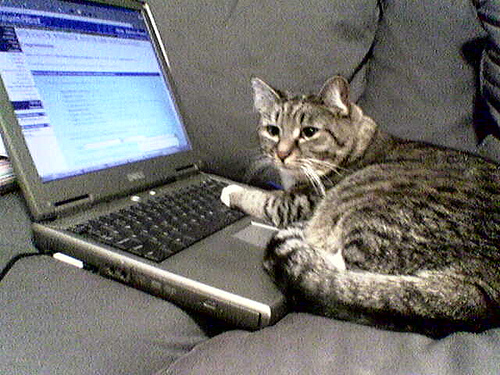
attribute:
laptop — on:
[3, 1, 215, 205]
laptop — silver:
[0, 1, 317, 332]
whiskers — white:
[240, 157, 343, 206]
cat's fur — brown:
[201, 67, 498, 332]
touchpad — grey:
[234, 221, 287, 249]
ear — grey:
[315, 72, 353, 115]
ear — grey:
[247, 70, 288, 113]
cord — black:
[4, 247, 54, 282]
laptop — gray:
[7, 0, 307, 307]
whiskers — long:
[229, 146, 341, 191]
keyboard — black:
[118, 152, 268, 274]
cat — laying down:
[231, 72, 480, 291]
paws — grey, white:
[215, 180, 275, 222]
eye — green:
[258, 122, 281, 139]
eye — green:
[296, 125, 318, 141]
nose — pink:
[275, 140, 294, 160]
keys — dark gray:
[59, 177, 249, 265]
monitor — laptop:
[0, 1, 206, 218]